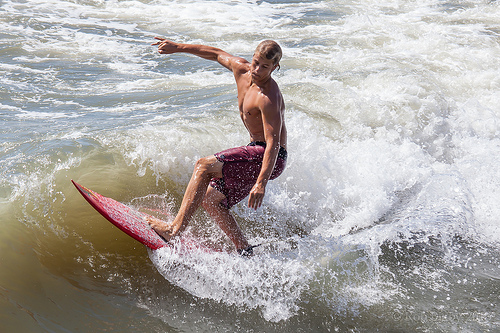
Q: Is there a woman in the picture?
A: No, there are no women.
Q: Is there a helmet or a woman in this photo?
A: No, there are no women or helmets.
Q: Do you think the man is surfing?
A: Yes, the man is surfing.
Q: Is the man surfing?
A: Yes, the man is surfing.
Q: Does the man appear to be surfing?
A: Yes, the man is surfing.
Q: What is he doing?
A: The man is surfing.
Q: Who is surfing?
A: The man is surfing.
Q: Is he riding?
A: No, the man is surfing.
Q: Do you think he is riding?
A: No, the man is surfing.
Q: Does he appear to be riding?
A: No, the man is surfing.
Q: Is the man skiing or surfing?
A: The man is surfing.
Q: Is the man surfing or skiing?
A: The man is surfing.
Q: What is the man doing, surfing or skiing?
A: The man is surfing.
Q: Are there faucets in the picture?
A: No, there are no faucets.